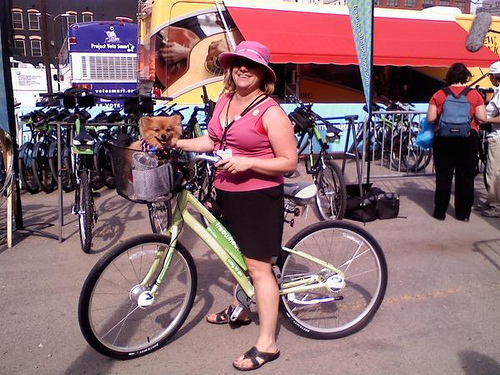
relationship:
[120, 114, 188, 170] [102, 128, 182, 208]
dog in a basket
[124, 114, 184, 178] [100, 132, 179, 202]
dog in a basket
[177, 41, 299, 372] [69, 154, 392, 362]
lady riding a bicycle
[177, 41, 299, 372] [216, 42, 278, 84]
lady wearing hat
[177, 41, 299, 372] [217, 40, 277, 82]
lady wearing pink hat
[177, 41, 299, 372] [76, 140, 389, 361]
lady on a bicycle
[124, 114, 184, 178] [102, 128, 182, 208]
dog in basket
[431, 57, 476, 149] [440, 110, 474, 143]
person wearing backpack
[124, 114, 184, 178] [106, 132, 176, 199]
dog in a basket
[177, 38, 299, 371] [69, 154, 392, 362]
lady with bicycle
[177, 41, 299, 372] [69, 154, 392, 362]
lady on bicycle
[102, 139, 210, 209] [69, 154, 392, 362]
basket on bicycle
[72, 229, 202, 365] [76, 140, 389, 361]
tire on bicycle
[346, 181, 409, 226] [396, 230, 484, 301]
bag on ground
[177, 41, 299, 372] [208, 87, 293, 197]
lady wears pink shirt